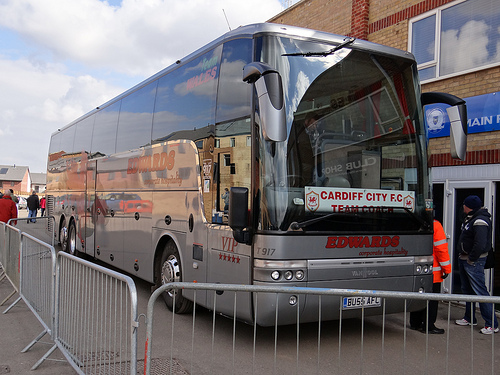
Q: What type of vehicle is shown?
A: A bus.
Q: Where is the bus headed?
A: Cardiff.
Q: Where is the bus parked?
A: Behind railings.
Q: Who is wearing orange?
A: The driver.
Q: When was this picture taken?
A: Morning.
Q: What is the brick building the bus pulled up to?
A: A station.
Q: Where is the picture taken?
A: A city bus stop.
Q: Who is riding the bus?
A: Cardiff City Football Club.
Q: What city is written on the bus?
A: Cardiff.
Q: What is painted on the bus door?
A: VIP.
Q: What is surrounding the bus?
A: Metal barrier.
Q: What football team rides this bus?
A: Cardiff City.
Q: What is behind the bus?
A: Brick building.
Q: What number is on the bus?
A: T 917.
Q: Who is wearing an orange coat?
A: Person next to bus.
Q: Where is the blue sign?
A: On the building.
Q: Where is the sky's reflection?
A: In the windows.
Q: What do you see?
A: A bus.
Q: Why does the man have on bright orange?
A: For safety reasons.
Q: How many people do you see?
A: At least six.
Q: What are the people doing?
A: Talking, standing and walking.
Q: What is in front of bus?
A: A gate.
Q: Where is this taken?
A: A bus station.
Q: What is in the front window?
A: A sign.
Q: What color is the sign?
A: White.